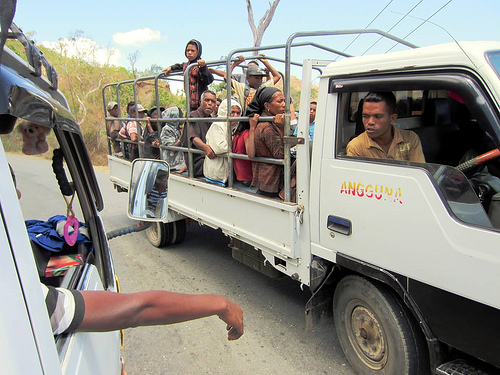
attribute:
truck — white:
[98, 19, 497, 373]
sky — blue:
[18, 2, 498, 70]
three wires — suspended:
[318, 1, 458, 66]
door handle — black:
[326, 214, 353, 235]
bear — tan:
[0, 101, 67, 174]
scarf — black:
[235, 84, 277, 140]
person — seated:
[156, 105, 188, 174]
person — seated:
[116, 102, 143, 160]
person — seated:
[181, 87, 216, 177]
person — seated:
[251, 85, 293, 199]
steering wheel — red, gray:
[453, 147, 499, 172]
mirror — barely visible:
[71, 151, 197, 269]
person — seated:
[201, 97, 241, 187]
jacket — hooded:
[166, 35, 213, 110]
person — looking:
[341, 93, 431, 167]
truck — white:
[110, 51, 496, 374]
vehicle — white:
[97, 25, 495, 373]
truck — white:
[98, 89, 469, 307]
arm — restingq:
[48, 201, 278, 354]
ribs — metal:
[92, 52, 334, 229]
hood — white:
[218, 97, 241, 123]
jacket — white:
[200, 96, 242, 185]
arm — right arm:
[52, 285, 245, 342]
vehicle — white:
[1, 2, 124, 374]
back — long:
[104, 26, 314, 298]